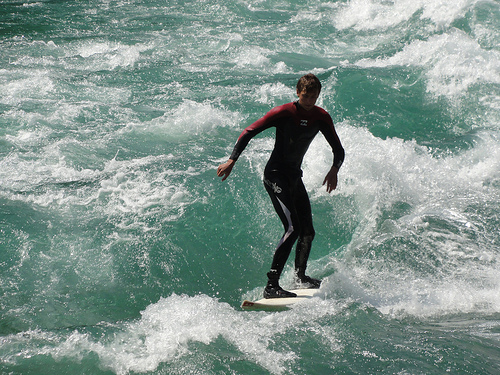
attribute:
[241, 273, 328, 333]
surfboard — wet, white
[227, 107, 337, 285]
wetsuit — wet, red, black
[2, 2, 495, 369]
water — wavy, large